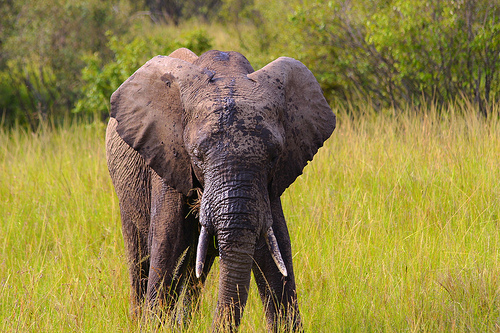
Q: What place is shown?
A: It is a field.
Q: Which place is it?
A: It is a field.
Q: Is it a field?
A: Yes, it is a field.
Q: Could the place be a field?
A: Yes, it is a field.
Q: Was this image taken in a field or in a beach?
A: It was taken at a field.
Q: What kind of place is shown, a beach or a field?
A: It is a field.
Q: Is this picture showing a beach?
A: No, the picture is showing a field.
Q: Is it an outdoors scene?
A: Yes, it is outdoors.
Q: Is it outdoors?
A: Yes, it is outdoors.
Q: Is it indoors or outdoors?
A: It is outdoors.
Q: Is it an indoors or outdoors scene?
A: It is outdoors.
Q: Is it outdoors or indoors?
A: It is outdoors.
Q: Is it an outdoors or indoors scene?
A: It is outdoors.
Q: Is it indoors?
A: No, it is outdoors.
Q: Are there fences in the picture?
A: No, there are no fences.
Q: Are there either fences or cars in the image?
A: No, there are no fences or cars.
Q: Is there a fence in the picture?
A: No, there are no fences.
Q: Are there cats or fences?
A: No, there are no fences or cats.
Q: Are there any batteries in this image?
A: No, there are no batteries.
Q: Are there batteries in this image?
A: No, there are no batteries.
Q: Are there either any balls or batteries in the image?
A: No, there are no batteries or balls.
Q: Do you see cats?
A: No, there are no cats.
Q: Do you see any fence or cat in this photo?
A: No, there are no cats or fences.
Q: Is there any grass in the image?
A: Yes, there is grass.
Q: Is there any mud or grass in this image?
A: Yes, there is grass.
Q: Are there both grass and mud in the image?
A: Yes, there are both grass and mud.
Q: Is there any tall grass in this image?
A: Yes, there is tall grass.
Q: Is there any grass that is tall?
A: Yes, there is grass that is tall.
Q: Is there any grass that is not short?
A: Yes, there is tall grass.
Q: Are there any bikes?
A: No, there are no bikes.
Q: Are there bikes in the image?
A: No, there are no bikes.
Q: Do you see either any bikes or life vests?
A: No, there are no bikes or life vests.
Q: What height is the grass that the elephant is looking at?
A: The grass is tall.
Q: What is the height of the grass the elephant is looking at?
A: The grass is tall.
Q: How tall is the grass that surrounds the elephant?
A: The grass is tall.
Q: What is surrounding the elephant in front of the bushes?
A: The grass is surrounding the elephant.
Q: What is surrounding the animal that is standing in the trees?
A: The grass is surrounding the elephant.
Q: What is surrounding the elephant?
A: The grass is surrounding the elephant.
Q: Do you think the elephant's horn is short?
A: Yes, the horn is short.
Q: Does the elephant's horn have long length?
A: No, the horn is short.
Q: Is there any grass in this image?
A: Yes, there is grass.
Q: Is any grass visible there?
A: Yes, there is grass.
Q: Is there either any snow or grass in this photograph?
A: Yes, there is grass.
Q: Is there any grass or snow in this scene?
A: Yes, there is grass.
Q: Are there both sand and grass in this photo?
A: No, there is grass but no sand.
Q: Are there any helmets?
A: No, there are no helmets.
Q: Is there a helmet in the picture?
A: No, there are no helmets.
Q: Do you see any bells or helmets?
A: No, there are no helmets or bells.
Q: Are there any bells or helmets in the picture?
A: No, there are no helmets or bells.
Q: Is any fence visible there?
A: No, there are no fences.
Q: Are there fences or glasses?
A: No, there are no fences or glasses.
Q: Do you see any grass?
A: Yes, there is grass.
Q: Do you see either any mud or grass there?
A: Yes, there is grass.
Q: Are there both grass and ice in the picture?
A: No, there is grass but no ice.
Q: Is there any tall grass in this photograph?
A: Yes, there is tall grass.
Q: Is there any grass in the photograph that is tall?
A: Yes, there is grass that is tall.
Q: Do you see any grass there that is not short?
A: Yes, there is tall grass.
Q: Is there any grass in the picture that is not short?
A: Yes, there is tall grass.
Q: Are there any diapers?
A: No, there are no diapers.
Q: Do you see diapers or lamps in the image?
A: No, there are no diapers or lamps.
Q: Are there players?
A: No, there are no players.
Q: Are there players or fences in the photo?
A: No, there are no players or fences.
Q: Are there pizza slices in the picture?
A: No, there are no pizza slices.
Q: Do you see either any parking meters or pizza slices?
A: No, there are no pizza slices or parking meters.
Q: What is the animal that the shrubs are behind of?
A: The animal is an elephant.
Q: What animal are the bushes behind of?
A: The shrubs are behind the elephant.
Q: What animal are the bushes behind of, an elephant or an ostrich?
A: The bushes are behind an elephant.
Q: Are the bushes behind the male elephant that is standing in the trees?
A: Yes, the bushes are behind the elephant.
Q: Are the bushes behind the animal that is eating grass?
A: Yes, the bushes are behind the elephant.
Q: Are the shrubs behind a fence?
A: No, the shrubs are behind the elephant.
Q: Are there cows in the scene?
A: No, there are no cows.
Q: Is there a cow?
A: No, there are no cows.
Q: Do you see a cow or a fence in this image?
A: No, there are no cows or fences.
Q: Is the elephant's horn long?
A: No, the horn is short.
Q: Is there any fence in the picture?
A: No, there are no fences.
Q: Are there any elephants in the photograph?
A: Yes, there is an elephant.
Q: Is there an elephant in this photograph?
A: Yes, there is an elephant.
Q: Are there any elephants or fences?
A: Yes, there is an elephant.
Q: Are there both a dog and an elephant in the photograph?
A: No, there is an elephant but no dogs.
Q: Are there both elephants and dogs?
A: No, there is an elephant but no dogs.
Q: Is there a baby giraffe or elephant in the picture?
A: Yes, there is a baby elephant.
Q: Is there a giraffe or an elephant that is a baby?
A: Yes, the elephant is a baby.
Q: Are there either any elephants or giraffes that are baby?
A: Yes, the elephant is a baby.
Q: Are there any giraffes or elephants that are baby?
A: Yes, the elephant is a baby.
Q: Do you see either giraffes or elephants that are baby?
A: Yes, the elephant is a baby.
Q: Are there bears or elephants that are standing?
A: Yes, the elephant is standing.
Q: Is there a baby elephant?
A: Yes, there is a baby elephant.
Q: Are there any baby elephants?
A: Yes, there is a baby elephant.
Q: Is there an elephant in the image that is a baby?
A: Yes, there is an elephant that is a baby.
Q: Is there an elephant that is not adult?
A: Yes, there is an baby elephant.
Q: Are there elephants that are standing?
A: Yes, there is an elephant that is standing.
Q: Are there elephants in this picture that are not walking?
A: Yes, there is an elephant that is standing.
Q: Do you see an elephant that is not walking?
A: Yes, there is an elephant that is standing .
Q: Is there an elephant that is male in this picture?
A: Yes, there is a male elephant.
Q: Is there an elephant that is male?
A: Yes, there is an elephant that is male.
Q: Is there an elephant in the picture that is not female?
A: Yes, there is a male elephant.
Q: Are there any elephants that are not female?
A: Yes, there is a male elephant.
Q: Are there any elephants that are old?
A: Yes, there is an old elephant.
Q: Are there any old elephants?
A: Yes, there is an old elephant.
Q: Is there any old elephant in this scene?
A: Yes, there is an old elephant.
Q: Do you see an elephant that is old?
A: Yes, there is an elephant that is old.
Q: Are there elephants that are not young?
A: Yes, there is a old elephant.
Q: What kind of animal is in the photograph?
A: The animal is an elephant.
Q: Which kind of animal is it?
A: The animal is an elephant.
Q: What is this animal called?
A: This is an elephant.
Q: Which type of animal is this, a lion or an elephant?
A: This is an elephant.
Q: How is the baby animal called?
A: The animal is an elephant.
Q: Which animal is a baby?
A: The animal is an elephant.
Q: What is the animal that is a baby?
A: The animal is an elephant.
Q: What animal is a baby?
A: The animal is an elephant.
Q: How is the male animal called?
A: The animal is an elephant.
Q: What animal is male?
A: The animal is an elephant.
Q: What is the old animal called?
A: The animal is an elephant.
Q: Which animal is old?
A: The animal is an elephant.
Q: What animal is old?
A: The animal is an elephant.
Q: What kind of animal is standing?
A: The animal is an elephant.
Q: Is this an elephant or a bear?
A: This is an elephant.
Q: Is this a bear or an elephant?
A: This is an elephant.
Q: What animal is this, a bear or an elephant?
A: This is an elephant.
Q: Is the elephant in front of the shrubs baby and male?
A: Yes, the elephant is a baby and male.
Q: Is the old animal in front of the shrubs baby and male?
A: Yes, the elephant is a baby and male.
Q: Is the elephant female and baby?
A: No, the elephant is a baby but male.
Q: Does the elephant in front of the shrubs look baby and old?
A: Yes, the elephant is a baby and old.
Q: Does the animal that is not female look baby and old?
A: Yes, the elephant is a baby and old.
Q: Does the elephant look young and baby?
A: No, the elephant is a baby but old.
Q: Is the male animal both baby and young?
A: No, the elephant is a baby but old.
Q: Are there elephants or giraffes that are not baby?
A: No, there is an elephant but he is a baby.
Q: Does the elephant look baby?
A: Yes, the elephant is a baby.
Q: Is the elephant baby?
A: Yes, the elephant is a baby.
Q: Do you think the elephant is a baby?
A: Yes, the elephant is a baby.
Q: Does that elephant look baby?
A: Yes, the elephant is a baby.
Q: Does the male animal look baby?
A: Yes, the elephant is a baby.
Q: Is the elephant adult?
A: No, the elephant is a baby.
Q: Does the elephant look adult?
A: No, the elephant is a baby.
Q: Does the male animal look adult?
A: No, the elephant is a baby.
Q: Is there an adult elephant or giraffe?
A: No, there is an elephant but he is a baby.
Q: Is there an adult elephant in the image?
A: No, there is an elephant but he is a baby.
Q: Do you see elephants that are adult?
A: No, there is an elephant but he is a baby.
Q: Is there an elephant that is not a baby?
A: No, there is an elephant but he is a baby.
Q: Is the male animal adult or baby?
A: The elephant is a baby.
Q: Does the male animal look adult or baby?
A: The elephant is a baby.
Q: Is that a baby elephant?
A: Yes, that is a baby elephant.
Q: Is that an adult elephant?
A: No, that is a baby elephant.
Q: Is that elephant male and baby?
A: Yes, the elephant is male and baby.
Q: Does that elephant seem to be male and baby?
A: Yes, the elephant is male and baby.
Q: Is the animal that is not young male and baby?
A: Yes, the elephant is male and baby.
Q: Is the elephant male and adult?
A: No, the elephant is male but baby.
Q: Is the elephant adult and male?
A: No, the elephant is male but baby.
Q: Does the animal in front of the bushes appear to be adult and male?
A: No, the elephant is male but baby.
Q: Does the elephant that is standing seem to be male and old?
A: Yes, the elephant is male and old.